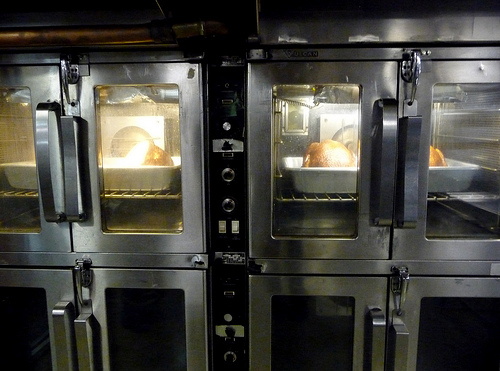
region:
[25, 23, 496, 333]
large commercial ovens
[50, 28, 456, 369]
large commercial ovens with silver doors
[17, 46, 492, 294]
large commercial ovens turned on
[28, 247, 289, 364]
large commercial ovens turned off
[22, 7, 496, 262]
large commercial ovens with double doors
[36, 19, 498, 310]
large commercial ovens with double silver doors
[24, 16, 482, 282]
doors on large commercial ovens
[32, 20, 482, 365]
silver doors large commercial ovens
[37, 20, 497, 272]
a light on in the ovens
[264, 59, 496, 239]
A light is on inside the windows.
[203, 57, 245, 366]
Switches are on a vertical panel.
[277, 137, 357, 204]
Food in a pan sitting on a rack.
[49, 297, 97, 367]
Two silver handles close together.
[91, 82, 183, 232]
Food cooking behind a glass window.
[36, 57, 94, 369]
Six silver handles on four doors.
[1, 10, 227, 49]
Copper pipe soldered into a fitting.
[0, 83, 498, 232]
Four observation windows in oven doors.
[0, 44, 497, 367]
Eight oven doors with silver handles.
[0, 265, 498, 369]
Four oven doors with blackened glass no light.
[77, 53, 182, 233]
This is an oven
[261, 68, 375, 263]
This is an oven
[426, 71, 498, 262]
This is an oven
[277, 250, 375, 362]
This is an oven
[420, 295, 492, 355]
This is an oven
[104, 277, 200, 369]
This is an oven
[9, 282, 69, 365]
This is an oven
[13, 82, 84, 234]
This is an oven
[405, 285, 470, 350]
This is an oven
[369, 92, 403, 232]
a metal door handle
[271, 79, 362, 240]
a window on the door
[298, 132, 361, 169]
a chicken in the pan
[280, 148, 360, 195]
a gray metal pan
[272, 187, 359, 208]
a gray metal grate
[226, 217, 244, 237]
a white switch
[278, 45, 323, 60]
a black sticker on the door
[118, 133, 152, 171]
light shining on the window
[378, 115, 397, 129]
light shining on the door handle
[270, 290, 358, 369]
a dark window